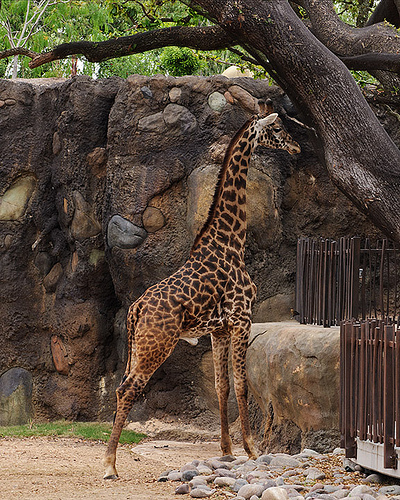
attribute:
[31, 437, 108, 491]
soil — by, dry, present, tan, brown, here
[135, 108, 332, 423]
giraffe — standing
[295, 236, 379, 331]
fence — metal, sticking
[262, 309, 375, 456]
stone — gray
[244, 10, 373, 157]
tree — thick, tall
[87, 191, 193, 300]
rock — large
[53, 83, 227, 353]
wall — confinement, stone, beside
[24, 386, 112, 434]
grass — patchy, green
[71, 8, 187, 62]
leaves — green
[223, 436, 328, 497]
stones — round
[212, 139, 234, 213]
hair — brown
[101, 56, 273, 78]
area — standing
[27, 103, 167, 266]
rocks — big, here, present, round, huge, large, larege